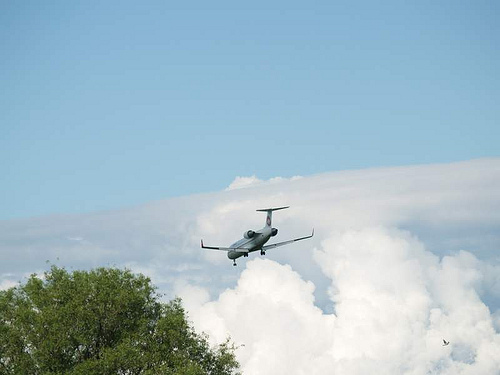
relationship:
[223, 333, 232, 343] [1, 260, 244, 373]
leaves on tree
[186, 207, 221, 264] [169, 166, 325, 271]
winglet on airplane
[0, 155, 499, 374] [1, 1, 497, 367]
cloud in sky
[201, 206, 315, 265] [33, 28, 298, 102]
aircraft flying air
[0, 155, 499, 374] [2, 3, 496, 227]
cloud in sky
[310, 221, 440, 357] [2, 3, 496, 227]
cloud in sky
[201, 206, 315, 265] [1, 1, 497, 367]
aircraft in sky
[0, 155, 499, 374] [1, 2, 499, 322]
cloud in sky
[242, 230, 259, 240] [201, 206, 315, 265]
engine on aircraft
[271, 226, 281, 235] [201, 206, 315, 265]
engine on aircraft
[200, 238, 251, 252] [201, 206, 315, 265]
winglet on aircraft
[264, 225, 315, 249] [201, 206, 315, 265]
wing on aircraft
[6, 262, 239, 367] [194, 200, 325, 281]
top near plane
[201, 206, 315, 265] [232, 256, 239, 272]
aircraft with gear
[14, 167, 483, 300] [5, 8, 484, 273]
bank in sky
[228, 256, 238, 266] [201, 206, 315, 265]
gear of aircraft